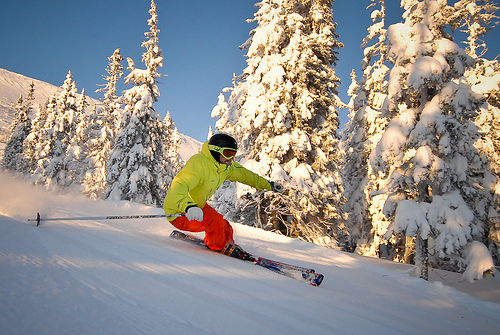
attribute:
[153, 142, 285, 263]
man — skiing, speeding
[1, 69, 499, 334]
hill — steep, snow covered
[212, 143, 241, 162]
goggles — yellow, orange, neon yellow, black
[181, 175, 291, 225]
gloves — white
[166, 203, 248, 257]
pants — orange, bright red, red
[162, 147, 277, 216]
jacket — yellow, neon yellow, bright yellow, padded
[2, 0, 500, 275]
trees — snow covered, tall, evergreens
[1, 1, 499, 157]
sky — bright, blue, clear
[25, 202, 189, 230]
ski pole — black, white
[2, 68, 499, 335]
snow — white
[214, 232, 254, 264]
boots — black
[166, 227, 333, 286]
skis — white, red, blue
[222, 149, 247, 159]
lenses — red